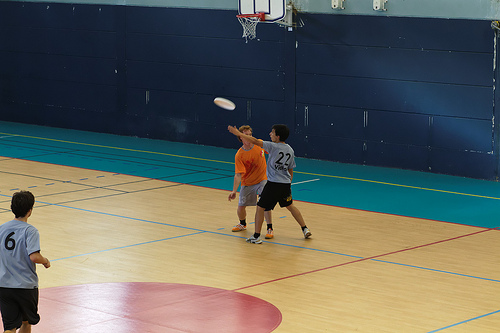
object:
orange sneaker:
[265, 228, 274, 238]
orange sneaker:
[230, 225, 245, 231]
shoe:
[303, 228, 312, 238]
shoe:
[245, 235, 262, 244]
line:
[46, 228, 490, 333]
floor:
[4, 144, 487, 331]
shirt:
[261, 141, 297, 184]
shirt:
[234, 145, 269, 187]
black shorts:
[256, 179, 292, 210]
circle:
[1, 282, 283, 333]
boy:
[229, 125, 313, 245]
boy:
[229, 125, 276, 239]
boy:
[1, 190, 52, 333]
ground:
[395, 117, 439, 147]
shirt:
[1, 219, 40, 290]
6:
[4, 231, 16, 251]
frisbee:
[213, 97, 236, 110]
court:
[0, 0, 499, 333]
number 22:
[275, 152, 291, 167]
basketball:
[235, 12, 264, 42]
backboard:
[237, 0, 287, 24]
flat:
[0, 119, 499, 333]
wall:
[0, 0, 500, 183]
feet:
[232, 224, 248, 232]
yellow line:
[0, 131, 500, 200]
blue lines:
[2, 174, 498, 331]